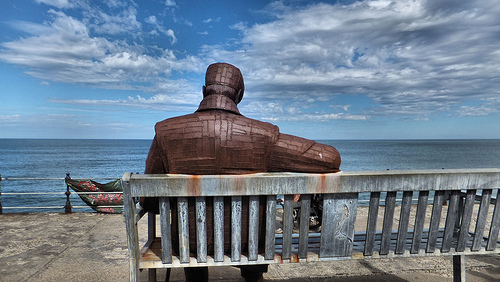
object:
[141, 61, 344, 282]
wooden figure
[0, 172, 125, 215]
fence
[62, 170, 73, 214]
post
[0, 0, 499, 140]
sky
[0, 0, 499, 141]
white clouds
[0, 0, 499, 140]
blue sky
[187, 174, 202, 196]
rust patch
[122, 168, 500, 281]
bench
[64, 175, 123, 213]
cloth